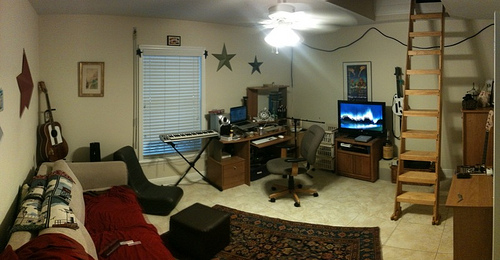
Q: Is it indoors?
A: Yes, it is indoors.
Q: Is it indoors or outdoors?
A: It is indoors.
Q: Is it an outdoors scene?
A: No, it is indoors.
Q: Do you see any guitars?
A: Yes, there is a guitar.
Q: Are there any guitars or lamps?
A: Yes, there is a guitar.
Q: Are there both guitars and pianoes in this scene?
A: Yes, there are both a guitar and a piano.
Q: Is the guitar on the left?
A: Yes, the guitar is on the left of the image.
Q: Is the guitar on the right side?
A: No, the guitar is on the left of the image.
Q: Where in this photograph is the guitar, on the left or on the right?
A: The guitar is on the left of the image.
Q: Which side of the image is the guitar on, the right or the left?
A: The guitar is on the left of the image.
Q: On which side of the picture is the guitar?
A: The guitar is on the left of the image.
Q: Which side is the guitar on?
A: The guitar is on the left of the image.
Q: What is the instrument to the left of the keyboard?
A: The instrument is a guitar.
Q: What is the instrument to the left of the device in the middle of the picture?
A: The instrument is a guitar.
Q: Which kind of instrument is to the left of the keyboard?
A: The instrument is a guitar.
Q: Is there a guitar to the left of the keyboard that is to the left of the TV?
A: Yes, there is a guitar to the left of the keyboard.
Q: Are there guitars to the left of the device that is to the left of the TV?
A: Yes, there is a guitar to the left of the keyboard.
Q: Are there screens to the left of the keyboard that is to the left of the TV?
A: No, there is a guitar to the left of the keyboard.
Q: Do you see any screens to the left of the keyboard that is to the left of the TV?
A: No, there is a guitar to the left of the keyboard.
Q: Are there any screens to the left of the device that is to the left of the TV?
A: No, there is a guitar to the left of the keyboard.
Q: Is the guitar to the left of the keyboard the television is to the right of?
A: Yes, the guitar is to the left of the keyboard.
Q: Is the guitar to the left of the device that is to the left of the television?
A: Yes, the guitar is to the left of the keyboard.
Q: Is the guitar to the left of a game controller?
A: No, the guitar is to the left of the keyboard.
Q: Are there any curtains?
A: No, there are no curtains.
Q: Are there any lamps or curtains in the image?
A: No, there are no curtains or lamps.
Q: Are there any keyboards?
A: Yes, there is a keyboard.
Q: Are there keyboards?
A: Yes, there is a keyboard.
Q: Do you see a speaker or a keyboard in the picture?
A: Yes, there is a keyboard.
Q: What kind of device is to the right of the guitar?
A: The device is a keyboard.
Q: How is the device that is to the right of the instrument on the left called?
A: The device is a keyboard.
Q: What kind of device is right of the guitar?
A: The device is a keyboard.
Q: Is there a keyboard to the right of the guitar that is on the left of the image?
A: Yes, there is a keyboard to the right of the guitar.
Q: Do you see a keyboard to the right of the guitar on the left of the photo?
A: Yes, there is a keyboard to the right of the guitar.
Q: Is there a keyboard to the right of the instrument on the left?
A: Yes, there is a keyboard to the right of the guitar.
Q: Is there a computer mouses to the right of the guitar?
A: No, there is a keyboard to the right of the guitar.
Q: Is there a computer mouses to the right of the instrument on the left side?
A: No, there is a keyboard to the right of the guitar.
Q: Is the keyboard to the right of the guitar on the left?
A: Yes, the keyboard is to the right of the guitar.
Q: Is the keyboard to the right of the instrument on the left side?
A: Yes, the keyboard is to the right of the guitar.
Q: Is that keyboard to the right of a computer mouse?
A: No, the keyboard is to the right of the guitar.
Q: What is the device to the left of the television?
A: The device is a keyboard.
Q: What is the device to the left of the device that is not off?
A: The device is a keyboard.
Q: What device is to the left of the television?
A: The device is a keyboard.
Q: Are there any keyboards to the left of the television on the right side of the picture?
A: Yes, there is a keyboard to the left of the television.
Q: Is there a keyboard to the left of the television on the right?
A: Yes, there is a keyboard to the left of the television.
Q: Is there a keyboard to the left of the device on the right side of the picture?
A: Yes, there is a keyboard to the left of the television.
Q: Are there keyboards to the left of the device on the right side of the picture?
A: Yes, there is a keyboard to the left of the television.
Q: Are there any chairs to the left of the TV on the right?
A: No, there is a keyboard to the left of the TV.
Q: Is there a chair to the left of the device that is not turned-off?
A: No, there is a keyboard to the left of the TV.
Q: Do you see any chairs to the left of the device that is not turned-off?
A: No, there is a keyboard to the left of the TV.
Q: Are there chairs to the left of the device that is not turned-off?
A: No, there is a keyboard to the left of the TV.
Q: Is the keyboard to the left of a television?
A: Yes, the keyboard is to the left of a television.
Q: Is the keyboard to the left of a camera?
A: No, the keyboard is to the left of a television.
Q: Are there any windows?
A: Yes, there is a window.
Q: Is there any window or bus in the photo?
A: Yes, there is a window.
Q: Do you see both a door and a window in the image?
A: No, there is a window but no doors.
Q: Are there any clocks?
A: No, there are no clocks.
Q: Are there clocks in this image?
A: No, there are no clocks.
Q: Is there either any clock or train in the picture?
A: No, there are no clocks or trains.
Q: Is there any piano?
A: Yes, there is a piano.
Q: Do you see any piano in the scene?
A: Yes, there is a piano.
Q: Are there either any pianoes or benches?
A: Yes, there is a piano.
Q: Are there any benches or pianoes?
A: Yes, there is a piano.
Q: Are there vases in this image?
A: No, there are no vases.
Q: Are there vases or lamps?
A: No, there are no vases or lamps.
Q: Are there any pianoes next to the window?
A: Yes, there is a piano next to the window.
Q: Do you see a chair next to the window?
A: No, there is a piano next to the window.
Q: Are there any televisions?
A: Yes, there is a television.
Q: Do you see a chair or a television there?
A: Yes, there is a television.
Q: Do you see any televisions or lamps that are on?
A: Yes, the television is on.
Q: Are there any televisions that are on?
A: Yes, there is a television that is on.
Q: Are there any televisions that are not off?
A: Yes, there is a television that is on.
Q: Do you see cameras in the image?
A: No, there are no cameras.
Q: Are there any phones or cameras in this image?
A: No, there are no cameras or phones.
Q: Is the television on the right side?
A: Yes, the television is on the right of the image.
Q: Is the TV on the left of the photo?
A: No, the TV is on the right of the image.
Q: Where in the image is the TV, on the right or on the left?
A: The TV is on the right of the image.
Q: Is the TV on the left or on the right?
A: The TV is on the right of the image.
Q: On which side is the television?
A: The television is on the right of the image.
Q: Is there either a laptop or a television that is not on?
A: No, there is a television but it is on.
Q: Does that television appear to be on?
A: Yes, the television is on.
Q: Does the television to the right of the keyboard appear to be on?
A: Yes, the television is on.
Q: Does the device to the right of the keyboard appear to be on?
A: Yes, the television is on.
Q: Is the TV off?
A: No, the TV is on.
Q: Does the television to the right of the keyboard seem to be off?
A: No, the TV is on.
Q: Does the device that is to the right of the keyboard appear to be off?
A: No, the TV is on.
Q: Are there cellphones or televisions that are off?
A: No, there is a television but it is on.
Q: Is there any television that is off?
A: No, there is a television but it is on.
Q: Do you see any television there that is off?
A: No, there is a television but it is on.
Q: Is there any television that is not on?
A: No, there is a television but it is on.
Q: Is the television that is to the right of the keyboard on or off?
A: The television is on.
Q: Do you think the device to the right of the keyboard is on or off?
A: The television is on.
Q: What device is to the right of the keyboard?
A: The device is a television.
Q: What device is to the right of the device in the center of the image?
A: The device is a television.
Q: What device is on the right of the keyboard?
A: The device is a television.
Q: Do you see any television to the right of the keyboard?
A: Yes, there is a television to the right of the keyboard.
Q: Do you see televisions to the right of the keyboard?
A: Yes, there is a television to the right of the keyboard.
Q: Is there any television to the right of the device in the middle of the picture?
A: Yes, there is a television to the right of the keyboard.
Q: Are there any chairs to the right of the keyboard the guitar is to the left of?
A: No, there is a television to the right of the keyboard.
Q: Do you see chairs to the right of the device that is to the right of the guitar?
A: No, there is a television to the right of the keyboard.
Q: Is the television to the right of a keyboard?
A: Yes, the television is to the right of a keyboard.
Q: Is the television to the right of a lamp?
A: No, the television is to the right of a keyboard.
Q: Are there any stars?
A: Yes, there is a star.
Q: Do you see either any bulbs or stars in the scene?
A: Yes, there is a star.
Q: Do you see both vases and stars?
A: No, there is a star but no vases.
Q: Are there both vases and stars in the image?
A: No, there is a star but no vases.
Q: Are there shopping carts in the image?
A: No, there are no shopping carts.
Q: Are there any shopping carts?
A: No, there are no shopping carts.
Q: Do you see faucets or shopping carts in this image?
A: No, there are no shopping carts or faucets.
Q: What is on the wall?
A: The star is on the wall.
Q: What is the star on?
A: The star is on the wall.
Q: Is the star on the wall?
A: Yes, the star is on the wall.